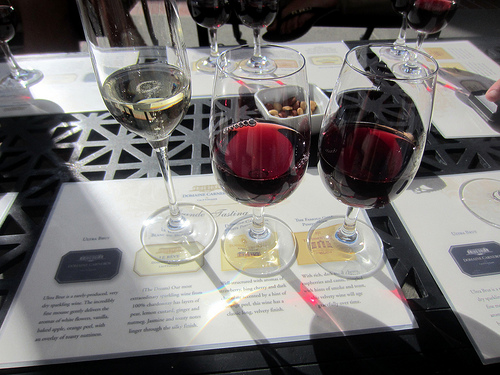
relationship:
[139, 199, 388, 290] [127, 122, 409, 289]
rim of  a glass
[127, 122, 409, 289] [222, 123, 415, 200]
glass of wine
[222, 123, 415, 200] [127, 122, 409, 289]
wine in glass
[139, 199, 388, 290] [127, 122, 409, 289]
rim of a glass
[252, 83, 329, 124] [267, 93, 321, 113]
bowl of nuts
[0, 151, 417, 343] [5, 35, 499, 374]
paper on table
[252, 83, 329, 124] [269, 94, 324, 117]
plate with nuts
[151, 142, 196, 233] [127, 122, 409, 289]
neck of glass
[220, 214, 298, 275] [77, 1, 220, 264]
base of glass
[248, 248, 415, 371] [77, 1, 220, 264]
shadow of glass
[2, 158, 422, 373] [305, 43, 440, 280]
placemat under glass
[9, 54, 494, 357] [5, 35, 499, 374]
menus on table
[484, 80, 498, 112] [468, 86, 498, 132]
finger on machine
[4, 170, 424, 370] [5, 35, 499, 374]
menu on top of table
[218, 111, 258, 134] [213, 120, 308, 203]
bubbles in wine